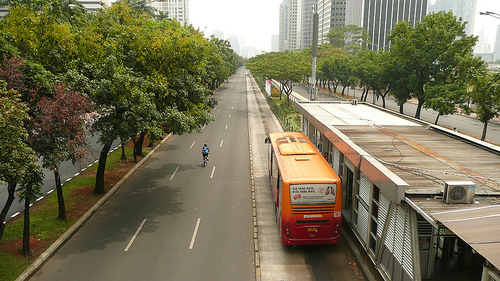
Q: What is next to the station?
A: A bus is next to a bus station.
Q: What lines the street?
A: Tall trees lines the street.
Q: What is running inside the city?
A: 3 lane roadway running inside a city.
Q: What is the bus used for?
A: An orange bus used for public transportation.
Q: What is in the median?
A: Row of beautiful trees planted in the median of a highway.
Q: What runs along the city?
A: Trees running along the stretch of a city road.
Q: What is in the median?
A: Rows of trees in the median of a rural street.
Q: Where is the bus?
A: A lane specific for public transportation via bus.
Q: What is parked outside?
A: A parked orange bus.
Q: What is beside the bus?
A: An enclosed bus station.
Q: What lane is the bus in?
A: A bus only lane.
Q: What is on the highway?
A: A paved three lane highway.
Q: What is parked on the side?
A: A red bus parked on the side of the street.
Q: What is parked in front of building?
A: Bus.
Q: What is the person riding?
A: Bike.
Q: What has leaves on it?
A: Trees.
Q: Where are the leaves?
A: On trees.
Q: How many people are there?
A: One.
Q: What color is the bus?
A: Orange.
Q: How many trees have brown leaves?
A: One.